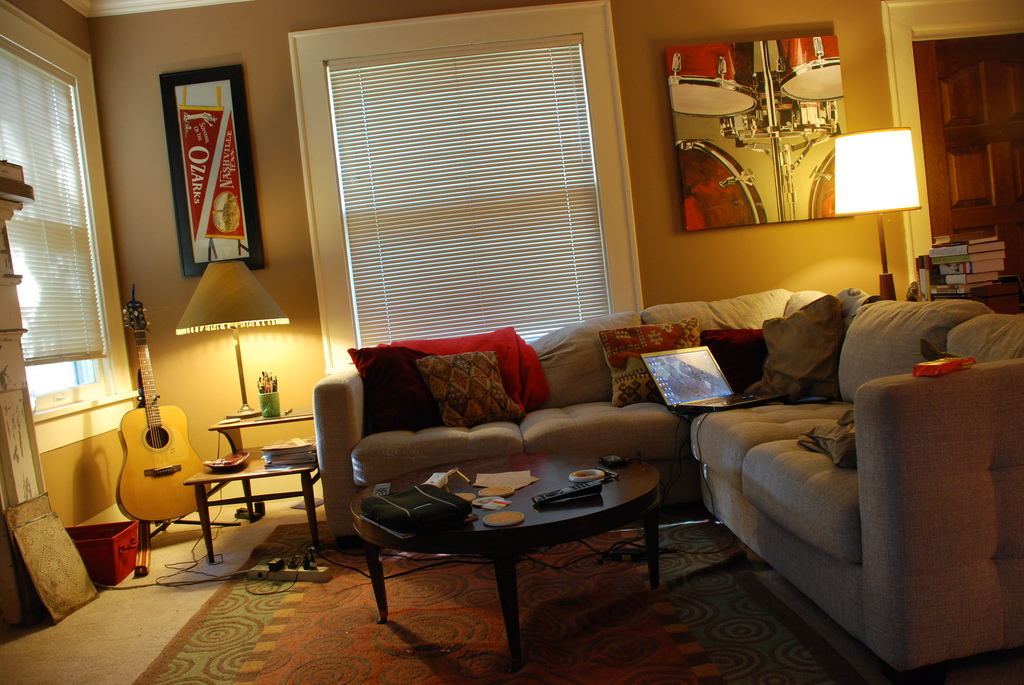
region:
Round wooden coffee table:
[353, 446, 668, 661]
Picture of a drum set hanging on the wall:
[657, 33, 873, 229]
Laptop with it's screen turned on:
[637, 344, 790, 412]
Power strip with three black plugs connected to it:
[246, 542, 336, 594]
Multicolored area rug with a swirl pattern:
[137, 512, 880, 683]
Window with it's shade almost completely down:
[0, 1, 153, 447]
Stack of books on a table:
[906, 219, 1015, 321]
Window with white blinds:
[286, 0, 659, 392]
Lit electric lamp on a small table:
[176, 256, 328, 510]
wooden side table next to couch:
[182, 408, 328, 565]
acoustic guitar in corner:
[108, 292, 214, 524]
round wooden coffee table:
[347, 447, 668, 647]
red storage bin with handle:
[68, 517, 145, 588]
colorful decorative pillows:
[343, 326, 553, 438]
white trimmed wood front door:
[881, 1, 1022, 312]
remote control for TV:
[533, 478, 606, 511]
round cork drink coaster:
[480, 504, 526, 534]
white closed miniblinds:
[319, 29, 615, 356]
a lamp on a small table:
[166, 267, 277, 414]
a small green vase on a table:
[242, 363, 294, 418]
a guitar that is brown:
[102, 302, 220, 524]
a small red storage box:
[89, 508, 157, 576]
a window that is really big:
[315, 42, 594, 327]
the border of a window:
[280, 147, 363, 227]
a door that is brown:
[908, 52, 1011, 223]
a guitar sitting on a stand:
[111, 298, 209, 520]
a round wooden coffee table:
[343, 456, 663, 665]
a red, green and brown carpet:
[137, 511, 856, 682]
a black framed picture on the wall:
[152, 61, 266, 283]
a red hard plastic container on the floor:
[61, 521, 141, 585]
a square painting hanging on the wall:
[661, 30, 855, 231]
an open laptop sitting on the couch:
[637, 344, 783, 411]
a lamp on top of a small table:
[174, 263, 288, 420]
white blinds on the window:
[313, 40, 612, 347]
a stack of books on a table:
[934, 235, 1007, 292]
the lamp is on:
[177, 257, 282, 327]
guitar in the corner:
[114, 294, 204, 516]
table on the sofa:
[642, 346, 734, 413]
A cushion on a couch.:
[752, 422, 909, 559]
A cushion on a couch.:
[808, 279, 923, 374]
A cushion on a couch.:
[944, 296, 995, 350]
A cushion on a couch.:
[683, 386, 895, 463]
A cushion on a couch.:
[767, 286, 835, 350]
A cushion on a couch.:
[533, 302, 702, 373]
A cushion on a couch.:
[517, 380, 740, 444]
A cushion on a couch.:
[321, 421, 571, 475]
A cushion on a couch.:
[363, 340, 576, 411]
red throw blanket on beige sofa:
[349, 327, 547, 419]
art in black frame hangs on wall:
[159, 64, 265, 274]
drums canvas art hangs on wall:
[661, 34, 851, 227]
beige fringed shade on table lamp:
[175, 260, 292, 334]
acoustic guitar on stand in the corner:
[112, 283, 205, 521]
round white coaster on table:
[482, 507, 525, 528]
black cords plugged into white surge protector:
[248, 555, 328, 579]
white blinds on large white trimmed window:
[305, 30, 615, 347]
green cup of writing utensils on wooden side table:
[256, 368, 282, 416]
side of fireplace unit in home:
[5, 157, 105, 638]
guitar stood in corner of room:
[111, 284, 217, 535]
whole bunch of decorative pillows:
[344, 288, 870, 470]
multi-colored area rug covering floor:
[132, 508, 913, 683]